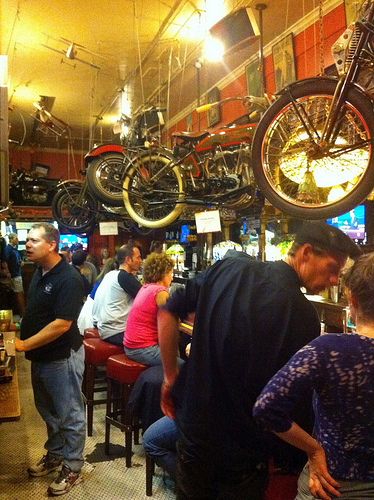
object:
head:
[24, 221, 62, 262]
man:
[1, 232, 26, 321]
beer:
[19, 257, 22, 265]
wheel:
[251, 74, 373, 221]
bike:
[251, 0, 374, 221]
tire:
[122, 152, 187, 230]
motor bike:
[124, 94, 298, 232]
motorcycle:
[120, 92, 299, 235]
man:
[155, 220, 366, 499]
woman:
[121, 251, 185, 367]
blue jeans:
[123, 344, 186, 367]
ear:
[301, 243, 313, 263]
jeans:
[31, 343, 88, 474]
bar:
[1, 0, 373, 499]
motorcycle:
[50, 142, 186, 234]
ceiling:
[1, 2, 341, 149]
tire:
[252, 75, 371, 220]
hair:
[141, 251, 176, 284]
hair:
[116, 242, 134, 262]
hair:
[341, 251, 374, 325]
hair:
[93, 257, 118, 282]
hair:
[32, 221, 60, 254]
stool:
[81, 337, 124, 439]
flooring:
[0, 387, 174, 499]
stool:
[105, 353, 150, 469]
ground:
[98, 0, 226, 77]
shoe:
[27, 459, 66, 477]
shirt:
[96, 266, 143, 342]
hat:
[294, 221, 364, 261]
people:
[0, 213, 374, 499]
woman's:
[0, 221, 188, 500]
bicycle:
[120, 92, 299, 229]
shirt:
[19, 252, 85, 363]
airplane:
[38, 32, 108, 71]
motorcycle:
[249, 0, 373, 220]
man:
[97, 243, 144, 346]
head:
[287, 220, 347, 296]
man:
[14, 221, 87, 499]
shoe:
[48, 463, 80, 499]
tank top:
[122, 282, 169, 350]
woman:
[157, 221, 374, 499]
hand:
[307, 450, 342, 500]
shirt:
[158, 247, 322, 468]